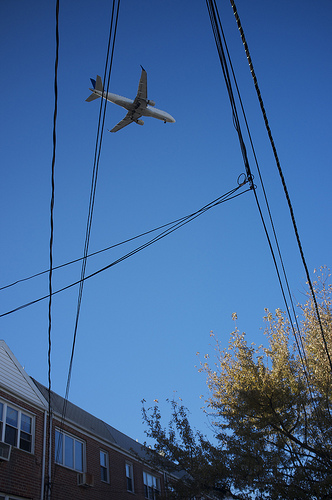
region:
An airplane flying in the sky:
[79, 60, 181, 135]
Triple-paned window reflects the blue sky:
[51, 424, 87, 473]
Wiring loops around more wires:
[234, 170, 259, 192]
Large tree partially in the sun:
[138, 263, 331, 498]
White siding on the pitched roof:
[0, 333, 53, 409]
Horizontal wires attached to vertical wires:
[235, 167, 259, 192]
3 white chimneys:
[128, 433, 170, 459]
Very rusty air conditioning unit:
[76, 470, 95, 490]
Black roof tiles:
[28, 375, 196, 485]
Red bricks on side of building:
[0, 384, 182, 498]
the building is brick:
[0, 331, 229, 498]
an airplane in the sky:
[36, 35, 259, 202]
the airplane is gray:
[78, 63, 179, 149]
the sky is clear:
[0, 0, 329, 220]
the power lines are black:
[194, 0, 327, 391]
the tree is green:
[129, 266, 327, 494]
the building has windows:
[0, 400, 183, 496]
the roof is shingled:
[30, 376, 196, 485]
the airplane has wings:
[81, 61, 175, 137]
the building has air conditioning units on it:
[0, 438, 99, 493]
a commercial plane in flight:
[73, 48, 196, 152]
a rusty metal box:
[73, 469, 97, 492]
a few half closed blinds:
[0, 397, 44, 432]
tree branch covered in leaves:
[128, 394, 253, 496]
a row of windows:
[33, 421, 167, 499]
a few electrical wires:
[44, 369, 76, 482]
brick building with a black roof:
[0, 381, 221, 498]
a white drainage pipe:
[37, 405, 52, 498]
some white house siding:
[1, 308, 61, 418]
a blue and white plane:
[77, 62, 204, 146]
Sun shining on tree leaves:
[201, 323, 322, 390]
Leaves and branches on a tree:
[150, 401, 324, 484]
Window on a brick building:
[54, 426, 86, 471]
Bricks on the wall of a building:
[13, 452, 39, 491]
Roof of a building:
[41, 385, 133, 446]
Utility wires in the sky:
[228, 141, 307, 250]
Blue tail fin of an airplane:
[88, 75, 96, 90]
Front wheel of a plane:
[162, 119, 168, 122]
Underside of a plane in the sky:
[87, 83, 174, 126]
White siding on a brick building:
[0, 340, 55, 414]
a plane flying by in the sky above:
[87, 67, 179, 137]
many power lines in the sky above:
[37, 2, 310, 394]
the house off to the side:
[4, 341, 195, 498]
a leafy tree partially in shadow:
[138, 284, 329, 496]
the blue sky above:
[1, 1, 329, 439]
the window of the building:
[51, 425, 87, 471]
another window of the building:
[140, 473, 158, 497]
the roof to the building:
[48, 393, 178, 475]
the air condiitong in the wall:
[77, 472, 96, 487]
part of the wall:
[23, 460, 73, 499]